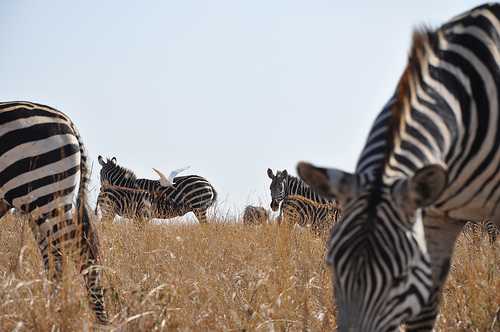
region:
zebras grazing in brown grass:
[22, 25, 484, 313]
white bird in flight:
[151, 159, 197, 196]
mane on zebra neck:
[375, 48, 440, 158]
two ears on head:
[286, 153, 458, 222]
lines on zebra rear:
[15, 122, 65, 200]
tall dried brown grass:
[154, 227, 269, 311]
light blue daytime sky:
[167, 40, 277, 125]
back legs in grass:
[35, 244, 110, 321]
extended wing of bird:
[165, 160, 198, 179]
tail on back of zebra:
[203, 180, 230, 213]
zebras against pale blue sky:
[10, 28, 488, 315]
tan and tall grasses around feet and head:
[31, 200, 458, 317]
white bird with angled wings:
[142, 160, 193, 195]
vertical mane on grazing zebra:
[340, 25, 450, 280]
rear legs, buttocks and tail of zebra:
[5, 87, 115, 319]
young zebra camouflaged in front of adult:
[81, 142, 213, 247]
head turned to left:
[260, 161, 330, 241]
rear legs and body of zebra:
[271, 180, 336, 246]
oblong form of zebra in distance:
[230, 200, 272, 235]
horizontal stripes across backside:
[3, 96, 83, 289]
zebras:
[3, 2, 499, 330]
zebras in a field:
[3, 3, 494, 330]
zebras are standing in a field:
[3, 0, 497, 330]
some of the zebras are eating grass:
[3, 1, 498, 325]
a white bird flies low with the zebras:
[151, 164, 196, 189]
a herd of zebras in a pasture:
[5, 8, 497, 328]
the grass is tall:
[0, 210, 495, 328]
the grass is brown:
[3, 200, 495, 330]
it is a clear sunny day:
[7, 2, 493, 322]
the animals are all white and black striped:
[7, 1, 497, 322]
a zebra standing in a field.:
[1, 82, 115, 319]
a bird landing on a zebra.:
[141, 147, 190, 204]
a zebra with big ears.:
[261, 162, 297, 211]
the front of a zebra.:
[104, 186, 161, 231]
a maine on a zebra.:
[294, 16, 469, 250]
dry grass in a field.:
[4, 207, 496, 329]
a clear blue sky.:
[1, 0, 498, 211]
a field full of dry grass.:
[1, 216, 498, 328]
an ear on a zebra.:
[366, 156, 471, 228]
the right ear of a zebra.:
[293, 154, 378, 214]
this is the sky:
[103, 28, 279, 116]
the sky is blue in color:
[140, 30, 241, 96]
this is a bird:
[153, 159, 183, 194]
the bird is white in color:
[168, 167, 173, 181]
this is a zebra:
[343, 139, 443, 329]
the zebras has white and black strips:
[428, 85, 481, 155]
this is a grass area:
[184, 240, 302, 327]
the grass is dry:
[169, 222, 274, 284]